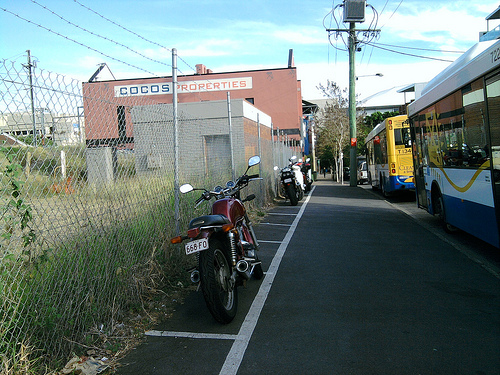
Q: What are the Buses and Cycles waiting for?
A: Riders.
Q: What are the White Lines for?
A: To show Desired Parking areas.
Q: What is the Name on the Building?
A: Cocos Properties.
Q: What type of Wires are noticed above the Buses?
A: Utility.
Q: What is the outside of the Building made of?
A: Brick.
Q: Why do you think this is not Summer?
A: Grass isn't Green enough.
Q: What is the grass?
A: Tall and green.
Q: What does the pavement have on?
A: The lines.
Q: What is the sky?
A: Blue and cloudy.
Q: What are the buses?
A: Parked.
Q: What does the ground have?
A: Shadows.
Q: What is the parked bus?
A: White and blue.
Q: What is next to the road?
A: The power pole.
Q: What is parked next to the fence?
A: A red motorcycle.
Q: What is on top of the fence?
A: Barbed wire.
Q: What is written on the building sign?
A: Cocos properties.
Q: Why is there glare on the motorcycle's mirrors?
A: The sun is shining on them.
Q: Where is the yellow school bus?
A: In front of the white bus.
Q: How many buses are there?
A: Two.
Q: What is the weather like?
A: Sunny.